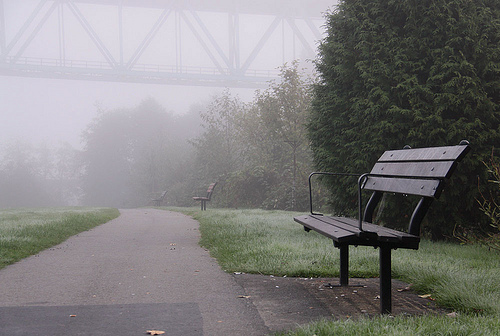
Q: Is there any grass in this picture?
A: Yes, there is grass.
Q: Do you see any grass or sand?
A: Yes, there is grass.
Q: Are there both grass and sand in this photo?
A: No, there is grass but no sand.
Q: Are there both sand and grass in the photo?
A: No, there is grass but no sand.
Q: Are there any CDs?
A: No, there are no cds.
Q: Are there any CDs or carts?
A: No, there are no CDs or carts.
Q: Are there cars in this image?
A: No, there are no cars.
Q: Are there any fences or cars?
A: No, there are no cars or fences.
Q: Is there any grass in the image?
A: Yes, there is grass.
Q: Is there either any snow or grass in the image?
A: Yes, there is grass.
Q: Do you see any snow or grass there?
A: Yes, there is grass.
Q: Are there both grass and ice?
A: No, there is grass but no ice.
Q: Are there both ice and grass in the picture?
A: No, there is grass but no ice.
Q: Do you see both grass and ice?
A: No, there is grass but no ice.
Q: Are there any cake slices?
A: No, there are no cake slices.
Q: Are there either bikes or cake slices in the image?
A: No, there are no cake slices or bikes.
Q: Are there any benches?
A: Yes, there is a bench.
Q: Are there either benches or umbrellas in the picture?
A: Yes, there is a bench.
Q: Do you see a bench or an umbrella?
A: Yes, there is a bench.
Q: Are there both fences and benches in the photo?
A: No, there is a bench but no fences.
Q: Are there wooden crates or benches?
A: Yes, there is a wood bench.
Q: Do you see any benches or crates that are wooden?
A: Yes, the bench is wooden.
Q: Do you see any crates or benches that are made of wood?
A: Yes, the bench is made of wood.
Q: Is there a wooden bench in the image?
A: Yes, there is a wood bench.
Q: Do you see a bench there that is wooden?
A: Yes, there is a bench that is wooden.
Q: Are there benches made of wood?
A: Yes, there is a bench that is made of wood.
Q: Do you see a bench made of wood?
A: Yes, there is a bench that is made of wood.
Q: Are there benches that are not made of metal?
A: Yes, there is a bench that is made of wood.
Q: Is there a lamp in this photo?
A: No, there are no lamps.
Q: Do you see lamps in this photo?
A: No, there are no lamps.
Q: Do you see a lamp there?
A: No, there are no lamps.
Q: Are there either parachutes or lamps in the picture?
A: No, there are no lamps or parachutes.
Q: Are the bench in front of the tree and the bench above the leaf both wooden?
A: Yes, both the bench and the bench are wooden.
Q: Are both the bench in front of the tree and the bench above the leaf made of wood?
A: Yes, both the bench and the bench are made of wood.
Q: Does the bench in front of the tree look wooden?
A: Yes, the bench is wooden.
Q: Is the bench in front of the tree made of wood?
A: Yes, the bench is made of wood.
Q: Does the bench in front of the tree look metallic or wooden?
A: The bench is wooden.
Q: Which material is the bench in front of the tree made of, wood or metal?
A: The bench is made of wood.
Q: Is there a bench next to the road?
A: Yes, there is a bench next to the road.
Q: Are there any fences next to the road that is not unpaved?
A: No, there is a bench next to the road.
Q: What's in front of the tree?
A: The bench is in front of the tree.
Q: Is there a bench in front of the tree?
A: Yes, there is a bench in front of the tree.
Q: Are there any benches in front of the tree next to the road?
A: Yes, there is a bench in front of the tree.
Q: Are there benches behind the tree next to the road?
A: No, the bench is in front of the tree.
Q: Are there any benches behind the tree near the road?
A: No, the bench is in front of the tree.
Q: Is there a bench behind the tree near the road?
A: No, the bench is in front of the tree.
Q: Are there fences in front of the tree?
A: No, there is a bench in front of the tree.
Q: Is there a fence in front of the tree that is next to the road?
A: No, there is a bench in front of the tree.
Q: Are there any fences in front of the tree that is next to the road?
A: No, there is a bench in front of the tree.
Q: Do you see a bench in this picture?
A: Yes, there is a bench.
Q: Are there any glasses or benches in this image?
A: Yes, there is a bench.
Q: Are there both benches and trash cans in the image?
A: No, there is a bench but no trash cans.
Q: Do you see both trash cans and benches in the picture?
A: No, there is a bench but no trash cans.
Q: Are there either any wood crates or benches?
A: Yes, there is a wood bench.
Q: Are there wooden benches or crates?
A: Yes, there is a wood bench.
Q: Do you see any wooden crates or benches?
A: Yes, there is a wood bench.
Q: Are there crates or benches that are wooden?
A: Yes, the bench is wooden.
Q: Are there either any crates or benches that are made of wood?
A: Yes, the bench is made of wood.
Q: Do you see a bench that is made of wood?
A: Yes, there is a bench that is made of wood.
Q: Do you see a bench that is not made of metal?
A: Yes, there is a bench that is made of wood.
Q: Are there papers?
A: No, there are no papers.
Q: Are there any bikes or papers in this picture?
A: No, there are no papers or bikes.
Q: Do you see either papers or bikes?
A: No, there are no papers or bikes.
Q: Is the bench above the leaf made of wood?
A: Yes, the bench is made of wood.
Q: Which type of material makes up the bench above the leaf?
A: The bench is made of wood.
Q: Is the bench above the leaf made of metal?
A: No, the bench is made of wood.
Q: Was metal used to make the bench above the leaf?
A: No, the bench is made of wood.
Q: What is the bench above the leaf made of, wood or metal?
A: The bench is made of wood.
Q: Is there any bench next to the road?
A: Yes, there is a bench next to the road.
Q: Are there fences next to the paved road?
A: No, there is a bench next to the road.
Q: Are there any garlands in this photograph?
A: No, there are no garlands.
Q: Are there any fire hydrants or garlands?
A: No, there are no garlands or fire hydrants.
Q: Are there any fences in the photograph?
A: No, there are no fences.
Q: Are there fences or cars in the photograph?
A: No, there are no fences or cars.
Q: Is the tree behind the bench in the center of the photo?
A: Yes, the tree is behind the bench.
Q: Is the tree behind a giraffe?
A: No, the tree is behind the bench.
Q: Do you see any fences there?
A: No, there are no fences.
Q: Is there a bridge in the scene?
A: Yes, there is a bridge.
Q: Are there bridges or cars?
A: Yes, there is a bridge.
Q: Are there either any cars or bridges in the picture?
A: Yes, there is a bridge.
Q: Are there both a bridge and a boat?
A: No, there is a bridge but no boats.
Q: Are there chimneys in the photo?
A: No, there are no chimneys.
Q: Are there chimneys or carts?
A: No, there are no chimneys or carts.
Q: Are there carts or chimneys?
A: No, there are no chimneys or carts.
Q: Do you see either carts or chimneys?
A: No, there are no chimneys or carts.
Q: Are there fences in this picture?
A: No, there are no fences.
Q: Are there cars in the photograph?
A: No, there are no cars.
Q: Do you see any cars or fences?
A: No, there are no cars or fences.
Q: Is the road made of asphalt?
A: Yes, the road is made of asphalt.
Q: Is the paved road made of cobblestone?
A: No, the road is made of asphalt.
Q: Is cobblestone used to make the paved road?
A: No, the road is made of asphalt.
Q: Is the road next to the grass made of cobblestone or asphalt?
A: The road is made of asphalt.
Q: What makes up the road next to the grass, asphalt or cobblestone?
A: The road is made of asphalt.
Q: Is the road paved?
A: Yes, the road is paved.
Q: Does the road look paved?
A: Yes, the road is paved.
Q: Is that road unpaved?
A: No, the road is paved.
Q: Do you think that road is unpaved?
A: No, the road is paved.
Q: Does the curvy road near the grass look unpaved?
A: No, the road is paved.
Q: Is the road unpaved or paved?
A: The road is paved.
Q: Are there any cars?
A: No, there are no cars.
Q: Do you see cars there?
A: No, there are no cars.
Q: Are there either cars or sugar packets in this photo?
A: No, there are no cars or sugar packets.